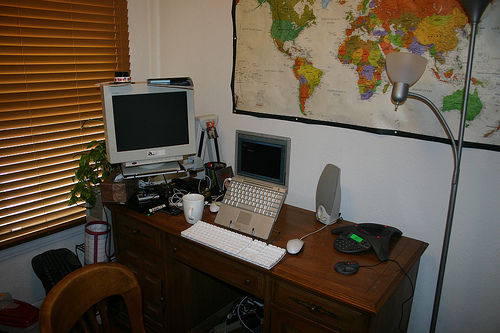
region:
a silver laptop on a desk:
[213, 113, 297, 241]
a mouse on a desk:
[285, 235, 305, 257]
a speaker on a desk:
[310, 154, 346, 226]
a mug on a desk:
[181, 192, 205, 224]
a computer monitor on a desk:
[93, 78, 199, 180]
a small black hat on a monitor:
[108, 66, 135, 86]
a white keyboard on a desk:
[175, 215, 287, 272]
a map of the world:
[227, 2, 499, 156]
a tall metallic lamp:
[381, 0, 491, 331]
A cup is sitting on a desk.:
[177, 190, 207, 225]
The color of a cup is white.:
[175, 190, 206, 226]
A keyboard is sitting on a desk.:
[176, 212, 291, 274]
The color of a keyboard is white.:
[174, 216, 288, 278]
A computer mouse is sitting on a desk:
[280, 214, 329, 264]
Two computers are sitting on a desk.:
[99, 68, 294, 248]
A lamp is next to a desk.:
[377, 0, 497, 331]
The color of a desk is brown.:
[98, 159, 430, 332]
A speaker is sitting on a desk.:
[304, 160, 348, 229]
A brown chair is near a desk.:
[33, 254, 148, 331]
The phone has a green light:
[320, 213, 400, 276]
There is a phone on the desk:
[324, 215, 409, 281]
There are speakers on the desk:
[302, 157, 347, 242]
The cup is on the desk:
[171, 185, 208, 240]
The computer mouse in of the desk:
[281, 220, 313, 268]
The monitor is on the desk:
[86, 61, 214, 181]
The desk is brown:
[88, 164, 445, 326]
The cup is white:
[168, 177, 215, 235]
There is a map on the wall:
[217, 1, 497, 159]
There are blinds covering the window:
[3, 5, 135, 257]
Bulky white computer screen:
[100, 80, 196, 179]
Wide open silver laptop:
[215, 125, 290, 239]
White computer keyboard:
[179, 218, 285, 273]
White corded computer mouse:
[285, 220, 326, 257]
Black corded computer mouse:
[332, 256, 414, 331]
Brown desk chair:
[35, 260, 153, 331]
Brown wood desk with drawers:
[102, 171, 428, 328]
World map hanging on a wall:
[225, 0, 498, 157]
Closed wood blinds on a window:
[0, 2, 132, 249]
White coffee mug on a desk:
[177, 191, 205, 223]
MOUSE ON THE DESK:
[285, 235, 304, 254]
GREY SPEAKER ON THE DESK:
[316, 163, 337, 225]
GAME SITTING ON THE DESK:
[333, 220, 399, 274]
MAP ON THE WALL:
[231, 0, 497, 125]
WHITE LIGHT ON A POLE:
[387, 49, 424, 96]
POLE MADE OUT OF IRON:
[453, 179, 458, 215]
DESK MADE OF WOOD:
[308, 266, 328, 283]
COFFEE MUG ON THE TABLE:
[181, 194, 204, 226]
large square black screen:
[98, 79, 200, 166]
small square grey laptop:
[215, 130, 292, 242]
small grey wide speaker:
[312, 161, 342, 226]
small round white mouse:
[286, 236, 303, 252]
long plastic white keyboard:
[179, 211, 289, 271]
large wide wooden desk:
[117, 199, 432, 332]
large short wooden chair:
[38, 261, 142, 330]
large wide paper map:
[232, 0, 499, 153]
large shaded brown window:
[2, 0, 133, 246]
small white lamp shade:
[385, 51, 430, 111]